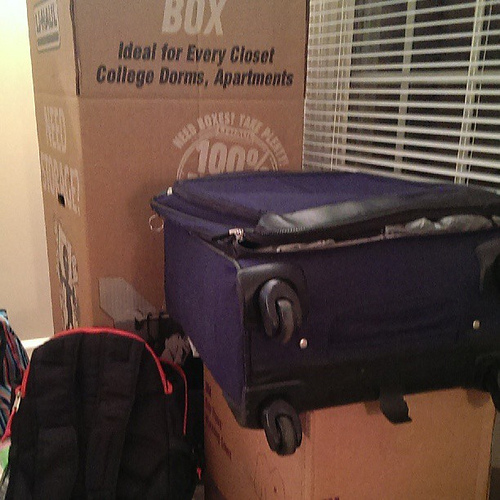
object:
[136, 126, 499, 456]
suitcase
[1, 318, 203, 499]
backpack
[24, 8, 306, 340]
box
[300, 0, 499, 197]
blind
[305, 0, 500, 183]
window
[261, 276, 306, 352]
wheel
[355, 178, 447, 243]
piece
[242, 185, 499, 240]
zipper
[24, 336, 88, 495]
straps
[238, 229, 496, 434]
bottom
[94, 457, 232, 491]
floor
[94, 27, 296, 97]
text